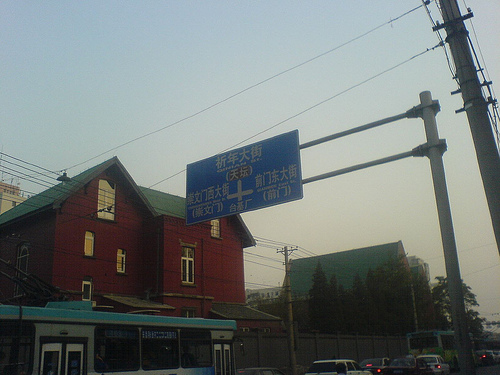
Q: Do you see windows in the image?
A: Yes, there is a window.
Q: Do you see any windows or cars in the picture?
A: Yes, there is a window.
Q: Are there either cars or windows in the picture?
A: Yes, there is a window.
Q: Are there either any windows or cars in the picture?
A: Yes, there is a window.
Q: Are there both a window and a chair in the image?
A: No, there is a window but no chairs.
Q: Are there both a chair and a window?
A: No, there is a window but no chairs.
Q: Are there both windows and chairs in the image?
A: No, there is a window but no chairs.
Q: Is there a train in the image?
A: No, there are no trains.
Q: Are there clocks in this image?
A: No, there are no clocks.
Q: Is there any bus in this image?
A: Yes, there is a bus.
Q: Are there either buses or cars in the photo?
A: Yes, there is a bus.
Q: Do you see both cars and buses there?
A: Yes, there are both a bus and a car.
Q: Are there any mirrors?
A: No, there are no mirrors.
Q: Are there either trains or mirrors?
A: No, there are no mirrors or trains.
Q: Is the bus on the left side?
A: Yes, the bus is on the left of the image.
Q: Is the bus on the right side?
A: No, the bus is on the left of the image.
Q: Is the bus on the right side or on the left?
A: The bus is on the left of the image.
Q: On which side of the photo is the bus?
A: The bus is on the left of the image.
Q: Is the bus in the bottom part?
A: Yes, the bus is in the bottom of the image.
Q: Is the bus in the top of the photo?
A: No, the bus is in the bottom of the image.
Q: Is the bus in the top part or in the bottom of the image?
A: The bus is in the bottom of the image.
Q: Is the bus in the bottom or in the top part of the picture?
A: The bus is in the bottom of the image.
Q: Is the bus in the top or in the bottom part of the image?
A: The bus is in the bottom of the image.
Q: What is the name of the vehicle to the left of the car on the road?
A: The vehicle is a bus.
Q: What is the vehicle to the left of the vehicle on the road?
A: The vehicle is a bus.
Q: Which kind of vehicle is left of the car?
A: The vehicle is a bus.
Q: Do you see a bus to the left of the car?
A: Yes, there is a bus to the left of the car.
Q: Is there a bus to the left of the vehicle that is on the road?
A: Yes, there is a bus to the left of the car.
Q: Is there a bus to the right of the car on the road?
A: No, the bus is to the left of the car.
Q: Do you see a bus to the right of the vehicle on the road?
A: No, the bus is to the left of the car.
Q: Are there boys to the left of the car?
A: No, there is a bus to the left of the car.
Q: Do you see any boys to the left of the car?
A: No, there is a bus to the left of the car.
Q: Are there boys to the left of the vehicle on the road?
A: No, there is a bus to the left of the car.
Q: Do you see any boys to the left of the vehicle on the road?
A: No, there is a bus to the left of the car.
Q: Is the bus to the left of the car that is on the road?
A: Yes, the bus is to the left of the car.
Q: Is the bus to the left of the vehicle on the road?
A: Yes, the bus is to the left of the car.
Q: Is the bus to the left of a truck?
A: No, the bus is to the left of the car.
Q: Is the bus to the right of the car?
A: No, the bus is to the left of the car.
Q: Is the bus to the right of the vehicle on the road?
A: No, the bus is to the left of the car.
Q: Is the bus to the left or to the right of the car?
A: The bus is to the left of the car.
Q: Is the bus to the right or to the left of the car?
A: The bus is to the left of the car.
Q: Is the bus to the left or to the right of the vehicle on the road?
A: The bus is to the left of the car.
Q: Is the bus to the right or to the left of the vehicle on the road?
A: The bus is to the left of the car.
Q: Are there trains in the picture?
A: No, there are no trains.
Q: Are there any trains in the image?
A: No, there are no trains.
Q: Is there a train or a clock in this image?
A: No, there are no trains or clocks.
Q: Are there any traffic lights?
A: No, there are no traffic lights.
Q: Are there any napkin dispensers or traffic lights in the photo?
A: No, there are no traffic lights or napkin dispensers.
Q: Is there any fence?
A: Yes, there is a fence.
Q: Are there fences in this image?
A: Yes, there is a fence.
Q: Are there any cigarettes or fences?
A: Yes, there is a fence.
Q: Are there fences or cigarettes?
A: Yes, there is a fence.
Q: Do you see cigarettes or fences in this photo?
A: Yes, there is a fence.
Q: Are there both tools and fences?
A: No, there is a fence but no tools.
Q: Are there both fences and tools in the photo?
A: No, there is a fence but no tools.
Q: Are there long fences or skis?
A: Yes, there is a long fence.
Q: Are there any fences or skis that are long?
A: Yes, the fence is long.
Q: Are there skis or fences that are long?
A: Yes, the fence is long.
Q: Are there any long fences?
A: Yes, there is a long fence.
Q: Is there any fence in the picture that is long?
A: Yes, there is a fence that is long.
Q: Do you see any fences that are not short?
A: Yes, there is a long fence.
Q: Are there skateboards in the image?
A: No, there are no skateboards.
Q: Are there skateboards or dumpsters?
A: No, there are no skateboards or dumpsters.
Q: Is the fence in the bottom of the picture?
A: Yes, the fence is in the bottom of the image.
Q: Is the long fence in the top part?
A: No, the fence is in the bottom of the image.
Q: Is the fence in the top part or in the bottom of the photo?
A: The fence is in the bottom of the image.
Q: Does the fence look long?
A: Yes, the fence is long.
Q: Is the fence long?
A: Yes, the fence is long.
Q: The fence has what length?
A: The fence is long.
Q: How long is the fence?
A: The fence is long.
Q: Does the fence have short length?
A: No, the fence is long.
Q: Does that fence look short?
A: No, the fence is long.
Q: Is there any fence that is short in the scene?
A: No, there is a fence but it is long.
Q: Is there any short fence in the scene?
A: No, there is a fence but it is long.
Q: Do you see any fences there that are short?
A: No, there is a fence but it is long.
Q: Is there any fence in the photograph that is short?
A: No, there is a fence but it is long.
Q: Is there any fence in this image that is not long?
A: No, there is a fence but it is long.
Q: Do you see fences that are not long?
A: No, there is a fence but it is long.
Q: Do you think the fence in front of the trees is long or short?
A: The fence is long.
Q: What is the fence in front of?
A: The fence is in front of the trees.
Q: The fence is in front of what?
A: The fence is in front of the trees.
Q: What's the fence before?
A: The fence is in front of the trees.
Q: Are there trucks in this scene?
A: No, there are no trucks.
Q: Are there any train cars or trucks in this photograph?
A: No, there are no trucks or train cars.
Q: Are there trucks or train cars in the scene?
A: No, there are no trucks or train cars.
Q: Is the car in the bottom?
A: Yes, the car is in the bottom of the image.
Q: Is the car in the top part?
A: No, the car is in the bottom of the image.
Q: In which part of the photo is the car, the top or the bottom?
A: The car is in the bottom of the image.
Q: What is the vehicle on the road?
A: The vehicle is a car.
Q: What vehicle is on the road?
A: The vehicle is a car.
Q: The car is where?
A: The car is on the road.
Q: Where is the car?
A: The car is on the road.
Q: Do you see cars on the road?
A: Yes, there is a car on the road.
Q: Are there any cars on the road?
A: Yes, there is a car on the road.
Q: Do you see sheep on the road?
A: No, there is a car on the road.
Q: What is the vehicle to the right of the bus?
A: The vehicle is a car.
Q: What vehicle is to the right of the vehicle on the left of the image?
A: The vehicle is a car.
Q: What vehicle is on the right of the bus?
A: The vehicle is a car.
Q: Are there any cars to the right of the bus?
A: Yes, there is a car to the right of the bus.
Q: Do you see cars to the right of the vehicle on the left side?
A: Yes, there is a car to the right of the bus.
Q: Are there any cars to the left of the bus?
A: No, the car is to the right of the bus.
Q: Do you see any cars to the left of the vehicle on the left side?
A: No, the car is to the right of the bus.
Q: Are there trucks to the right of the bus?
A: No, there is a car to the right of the bus.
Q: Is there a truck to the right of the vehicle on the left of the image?
A: No, there is a car to the right of the bus.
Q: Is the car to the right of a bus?
A: Yes, the car is to the right of a bus.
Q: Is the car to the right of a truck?
A: No, the car is to the right of a bus.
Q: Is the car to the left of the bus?
A: No, the car is to the right of the bus.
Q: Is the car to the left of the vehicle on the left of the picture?
A: No, the car is to the right of the bus.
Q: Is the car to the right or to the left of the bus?
A: The car is to the right of the bus.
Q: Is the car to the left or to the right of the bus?
A: The car is to the right of the bus.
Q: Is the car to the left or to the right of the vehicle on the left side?
A: The car is to the right of the bus.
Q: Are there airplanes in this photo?
A: No, there are no airplanes.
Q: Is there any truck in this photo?
A: No, there are no trucks.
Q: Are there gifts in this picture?
A: No, there are no gifts.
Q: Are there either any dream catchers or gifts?
A: No, there are no gifts or dream catchers.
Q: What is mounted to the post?
A: The sign is mounted to the post.